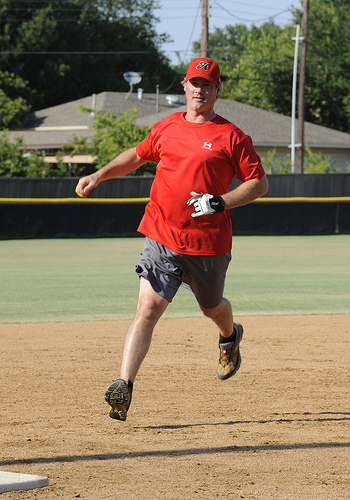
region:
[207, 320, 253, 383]
Grey and yellow shoe.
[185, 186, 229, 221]
Black and white glove on hand.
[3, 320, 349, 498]
Dirt on the ground.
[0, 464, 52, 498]
White baseball base on ground.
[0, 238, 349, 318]
Green grass in the background.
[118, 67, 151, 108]
Gray dish antenna on house.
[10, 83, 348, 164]
Gray house roof in background.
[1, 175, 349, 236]
Wooden fence in background.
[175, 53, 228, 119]
Orange baseball cap on man.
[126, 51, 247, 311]
Gray shorts on man.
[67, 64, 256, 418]
A fat man jogging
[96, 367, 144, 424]
Orange and grey sport shoe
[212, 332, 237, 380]
Orange and grey sport shoe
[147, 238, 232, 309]
A Grey jogging shorts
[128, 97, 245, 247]
An orange sport Tshirt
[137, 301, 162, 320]
A brown human kneel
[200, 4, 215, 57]
A wooden electricity pole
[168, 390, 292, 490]
A sandy playing field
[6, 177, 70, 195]
A wooden old fance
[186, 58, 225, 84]
An orange protective cap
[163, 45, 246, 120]
Red hat with an H on it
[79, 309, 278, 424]
Man with feet raised off the ground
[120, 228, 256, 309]
Men's gray athletic shorts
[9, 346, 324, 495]
Dirt baseball field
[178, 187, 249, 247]
Man's sports glove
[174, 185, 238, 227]
Black and white men's sport's glove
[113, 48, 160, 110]
Gray cable dish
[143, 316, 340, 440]
Man's shadow on a baseball field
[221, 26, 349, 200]
Tree behind a house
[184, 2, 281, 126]
Power pole behind a house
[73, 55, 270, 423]
a man running on field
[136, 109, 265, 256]
a man's red t-shirt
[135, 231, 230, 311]
a grey pair of shorts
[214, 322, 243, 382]
a grey and yellow tennis shoe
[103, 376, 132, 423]
a grey and yellow tennis shoe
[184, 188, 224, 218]
a black and white baseball glove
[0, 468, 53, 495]
a white base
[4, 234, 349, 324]
a green grassy field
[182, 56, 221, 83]
a red baseball hat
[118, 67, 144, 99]
a satellite dish in distance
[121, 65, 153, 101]
satelite dish on the roof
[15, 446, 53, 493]
baseball base in the dirt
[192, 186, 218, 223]
man is wearing a batting glove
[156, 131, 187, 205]
man is wearing a red shirt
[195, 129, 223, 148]
under armour written on the shirt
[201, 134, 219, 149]
under armour symbol is on the shirt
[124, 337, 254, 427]
man running to the base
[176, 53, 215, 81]
ball cap is red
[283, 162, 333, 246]
wooden fence against the trees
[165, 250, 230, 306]
man is wearing grey shorts